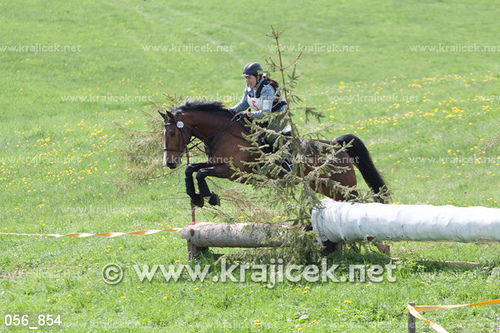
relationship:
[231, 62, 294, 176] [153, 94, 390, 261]
man on a horse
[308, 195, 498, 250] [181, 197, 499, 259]
wrapping on a pole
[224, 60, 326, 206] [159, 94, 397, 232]
man riding horse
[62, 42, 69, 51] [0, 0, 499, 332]
grass in field field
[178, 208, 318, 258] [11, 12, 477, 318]
poll on ground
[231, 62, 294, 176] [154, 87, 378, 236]
man on horse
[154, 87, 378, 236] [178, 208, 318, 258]
horse on poll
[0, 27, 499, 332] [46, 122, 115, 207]
grass has flowers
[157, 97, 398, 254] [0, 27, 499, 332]
horse on grass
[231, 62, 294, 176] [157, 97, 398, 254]
man on horse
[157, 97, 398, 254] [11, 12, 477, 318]
horse on ground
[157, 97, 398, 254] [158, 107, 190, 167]
horse has head